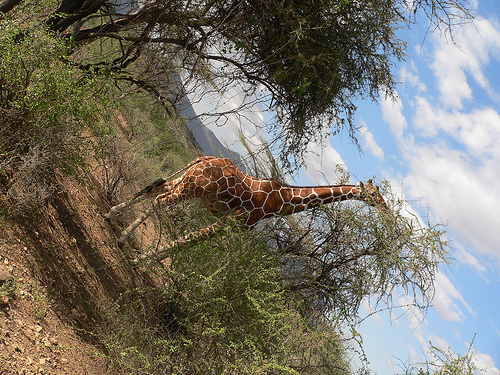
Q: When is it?
A: Day time.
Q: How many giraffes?
A: 1.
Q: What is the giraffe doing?
A: Eating.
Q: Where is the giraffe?
A: Field.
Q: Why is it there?
A: To eat.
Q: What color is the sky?
A: Blue.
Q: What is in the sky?
A: Clouds.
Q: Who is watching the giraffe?
A: People.